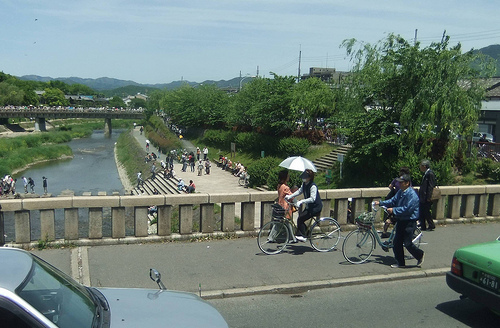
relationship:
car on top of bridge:
[444, 236, 499, 321] [0, 185, 498, 327]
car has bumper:
[444, 236, 499, 321] [446, 271, 500, 311]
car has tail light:
[444, 236, 499, 321] [450, 258, 463, 277]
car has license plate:
[444, 236, 499, 321] [476, 275, 498, 295]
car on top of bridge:
[1, 247, 231, 327] [0, 185, 498, 327]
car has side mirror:
[1, 247, 231, 327] [148, 268, 166, 291]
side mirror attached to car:
[148, 268, 166, 291] [1, 247, 231, 327]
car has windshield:
[1, 247, 231, 327] [16, 252, 95, 327]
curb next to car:
[194, 267, 451, 300] [444, 236, 499, 321]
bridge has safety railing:
[0, 185, 498, 327] [0, 183, 500, 249]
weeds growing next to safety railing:
[37, 234, 56, 251] [0, 183, 500, 249]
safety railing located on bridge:
[0, 183, 500, 249] [0, 185, 498, 327]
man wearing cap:
[372, 174, 426, 270] [395, 174, 412, 183]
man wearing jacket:
[372, 174, 426, 270] [379, 189, 421, 223]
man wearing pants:
[372, 174, 426, 270] [392, 220, 424, 265]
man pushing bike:
[372, 174, 426, 270] [342, 196, 424, 265]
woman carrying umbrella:
[268, 155, 316, 242] [277, 155, 318, 187]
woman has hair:
[268, 155, 316, 242] [276, 169, 288, 186]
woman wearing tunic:
[268, 155, 316, 242] [274, 186, 297, 222]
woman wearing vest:
[286, 168, 324, 243] [301, 185, 322, 211]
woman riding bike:
[286, 168, 324, 243] [257, 198, 343, 255]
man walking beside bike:
[372, 174, 426, 270] [342, 196, 424, 265]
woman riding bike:
[268, 155, 316, 242] [257, 198, 343, 255]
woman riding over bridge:
[286, 168, 324, 243] [0, 185, 498, 327]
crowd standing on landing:
[164, 144, 212, 176] [165, 159, 270, 231]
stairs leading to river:
[129, 168, 195, 194] [1, 128, 135, 242]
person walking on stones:
[41, 174, 49, 195] [0, 191, 130, 199]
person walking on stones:
[27, 177, 35, 194] [0, 191, 130, 199]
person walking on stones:
[21, 175, 29, 195] [0, 191, 130, 199]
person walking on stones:
[9, 177, 19, 195] [0, 191, 130, 199]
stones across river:
[0, 191, 130, 199] [1, 128, 135, 242]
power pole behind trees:
[297, 50, 303, 80] [148, 75, 338, 144]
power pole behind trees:
[238, 71, 243, 90] [148, 75, 338, 144]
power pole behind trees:
[255, 66, 261, 78] [148, 75, 338, 144]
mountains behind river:
[17, 75, 256, 94] [1, 128, 135, 242]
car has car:
[444, 236, 499, 321] [444, 238, 499, 310]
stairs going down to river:
[129, 168, 195, 194] [1, 128, 135, 242]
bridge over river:
[2, 105, 152, 136] [1, 128, 135, 242]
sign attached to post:
[335, 152, 345, 163] [338, 160, 343, 180]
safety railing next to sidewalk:
[0, 183, 500, 249] [4, 223, 499, 302]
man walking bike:
[372, 174, 426, 270] [342, 196, 424, 265]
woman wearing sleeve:
[286, 168, 324, 243] [295, 183, 318, 209]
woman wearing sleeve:
[286, 168, 324, 243] [289, 183, 305, 198]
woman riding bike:
[268, 155, 316, 242] [342, 196, 424, 265]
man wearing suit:
[414, 159, 438, 232] [418, 171, 436, 231]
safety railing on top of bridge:
[0, 183, 500, 249] [0, 185, 498, 327]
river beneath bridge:
[1, 128, 135, 242] [2, 105, 152, 136]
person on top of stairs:
[137, 169, 145, 192] [129, 168, 195, 194]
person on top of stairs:
[184, 179, 195, 194] [129, 168, 195, 194]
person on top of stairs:
[151, 163, 158, 181] [129, 168, 195, 194]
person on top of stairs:
[176, 178, 183, 192] [129, 168, 195, 194]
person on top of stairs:
[152, 186, 160, 195] [129, 168, 195, 194]